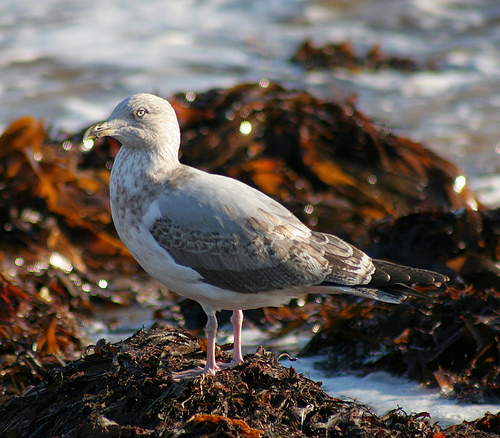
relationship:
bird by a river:
[80, 91, 455, 384] [4, 1, 499, 203]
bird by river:
[80, 91, 455, 384] [4, 1, 499, 203]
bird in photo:
[80, 91, 455, 384] [4, 4, 493, 436]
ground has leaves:
[5, 96, 499, 433] [180, 83, 470, 169]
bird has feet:
[80, 91, 455, 384] [167, 362, 221, 383]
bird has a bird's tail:
[80, 91, 455, 384] [282, 229, 449, 308]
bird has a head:
[80, 91, 455, 384] [88, 91, 180, 168]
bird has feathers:
[80, 91, 455, 384] [111, 165, 451, 320]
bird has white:
[80, 91, 455, 384] [102, 158, 235, 313]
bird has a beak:
[80, 91, 455, 384] [87, 121, 117, 142]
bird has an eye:
[80, 91, 455, 384] [136, 109, 146, 117]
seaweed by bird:
[180, 83, 470, 169] [80, 91, 455, 384]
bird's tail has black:
[282, 203, 449, 327] [370, 255, 449, 297]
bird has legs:
[80, 91, 455, 384] [171, 305, 245, 382]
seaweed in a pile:
[180, 83, 470, 169] [191, 89, 404, 174]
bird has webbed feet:
[80, 91, 455, 384] [166, 356, 245, 384]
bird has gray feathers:
[80, 91, 455, 384] [111, 165, 451, 320]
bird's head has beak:
[88, 91, 180, 168] [87, 121, 117, 142]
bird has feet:
[80, 91, 455, 384] [166, 356, 245, 384]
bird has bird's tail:
[80, 91, 455, 384] [282, 229, 449, 308]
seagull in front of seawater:
[80, 91, 455, 384] [4, 1, 499, 203]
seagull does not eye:
[80, 91, 455, 384] [136, 106, 146, 117]